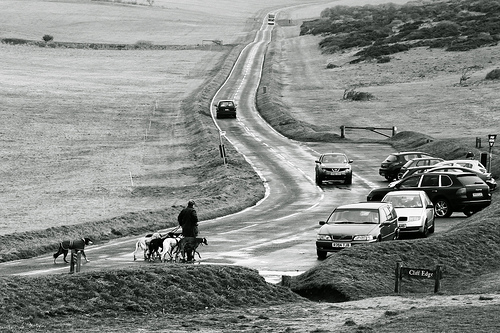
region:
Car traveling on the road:
[212, 98, 237, 118]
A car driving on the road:
[313, 153, 353, 185]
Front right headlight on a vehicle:
[316, 232, 331, 242]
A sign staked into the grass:
[392, 260, 444, 292]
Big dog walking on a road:
[52, 237, 94, 261]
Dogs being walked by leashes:
[133, 225, 210, 260]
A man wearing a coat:
[177, 200, 202, 235]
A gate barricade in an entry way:
[340, 124, 397, 140]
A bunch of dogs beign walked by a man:
[132, 201, 209, 263]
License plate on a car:
[332, 240, 352, 247]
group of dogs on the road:
[55, 227, 209, 264]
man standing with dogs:
[183, 199, 207, 260]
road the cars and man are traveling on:
[33, 0, 468, 285]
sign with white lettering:
[397, 262, 444, 289]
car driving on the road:
[208, 96, 357, 185]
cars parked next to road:
[318, 138, 495, 271]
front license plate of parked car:
[329, 239, 351, 251]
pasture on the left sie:
[2, 9, 213, 206]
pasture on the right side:
[301, 44, 498, 126]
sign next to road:
[388, 260, 441, 294]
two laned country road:
[16, 3, 356, 278]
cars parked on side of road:
[321, 149, 493, 253]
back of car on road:
[213, 98, 238, 120]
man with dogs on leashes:
[134, 200, 208, 260]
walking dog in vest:
[53, 235, 93, 263]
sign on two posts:
[392, 261, 442, 292]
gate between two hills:
[336, 125, 398, 141]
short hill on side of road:
[254, 41, 303, 137]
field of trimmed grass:
[2, 2, 231, 236]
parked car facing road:
[368, 171, 489, 218]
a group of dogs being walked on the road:
[133, 231, 209, 261]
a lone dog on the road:
[53, 235, 95, 265]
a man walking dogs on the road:
[177, 200, 202, 257]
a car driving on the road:
[215, 98, 237, 123]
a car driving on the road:
[310, 150, 357, 187]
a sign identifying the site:
[390, 261, 448, 296]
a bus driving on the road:
[266, 13, 277, 28]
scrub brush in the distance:
[298, 6, 498, 66]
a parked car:
[314, 201, 397, 258]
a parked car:
[366, 167, 494, 218]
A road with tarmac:
[240, 112, 309, 242]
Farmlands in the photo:
[81, 79, 164, 181]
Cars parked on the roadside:
[373, 137, 464, 238]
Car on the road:
[296, 138, 355, 200]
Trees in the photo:
[355, 2, 447, 32]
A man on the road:
[172, 197, 212, 233]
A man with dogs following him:
[134, 192, 214, 266]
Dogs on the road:
[122, 216, 212, 261]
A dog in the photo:
[45, 219, 102, 268]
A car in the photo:
[368, 168, 491, 211]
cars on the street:
[266, 119, 498, 277]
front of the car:
[282, 203, 390, 273]